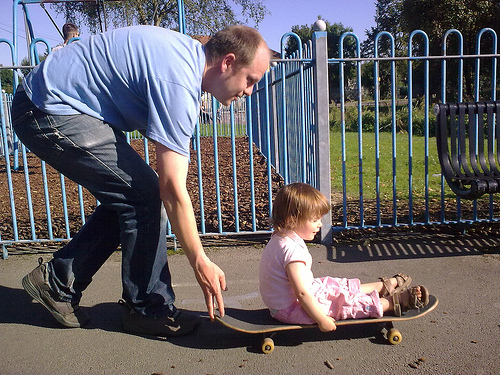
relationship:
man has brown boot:
[4, 21, 271, 339] [20, 262, 94, 335]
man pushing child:
[4, 21, 271, 339] [260, 182, 428, 342]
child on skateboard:
[260, 182, 428, 342] [213, 295, 438, 354]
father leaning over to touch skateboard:
[8, 25, 270, 339] [213, 288, 440, 353]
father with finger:
[8, 25, 270, 339] [203, 293, 215, 319]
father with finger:
[8, 25, 270, 339] [214, 292, 225, 319]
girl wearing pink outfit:
[257, 185, 429, 322] [260, 232, 384, 321]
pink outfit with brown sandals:
[260, 232, 384, 321] [379, 270, 430, 312]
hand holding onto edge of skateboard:
[315, 310, 345, 340] [210, 282, 443, 352]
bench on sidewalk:
[438, 98, 499, 211] [16, 235, 496, 367]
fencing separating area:
[5, 32, 496, 218] [333, 128, 437, 199]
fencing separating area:
[5, 32, 496, 218] [195, 136, 260, 219]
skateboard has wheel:
[215, 303, 442, 342] [258, 337, 276, 354]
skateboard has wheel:
[215, 303, 442, 342] [388, 326, 403, 346]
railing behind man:
[0, 12, 498, 260] [4, 21, 271, 339]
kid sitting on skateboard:
[249, 179, 364, 311] [185, 297, 496, 352]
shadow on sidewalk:
[318, 213, 478, 247] [16, 235, 496, 367]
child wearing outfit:
[260, 182, 428, 342] [257, 231, 385, 324]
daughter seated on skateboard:
[256, 182, 428, 329] [144, 257, 441, 372]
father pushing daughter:
[8, 25, 270, 339] [256, 182, 428, 329]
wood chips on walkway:
[302, 335, 499, 373] [5, 228, 499, 374]